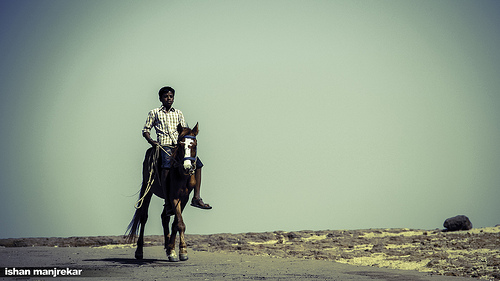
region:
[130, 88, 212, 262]
boy riding small horse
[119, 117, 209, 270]
horse with white blaze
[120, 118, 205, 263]
brown horse with white face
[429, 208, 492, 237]
single stone in field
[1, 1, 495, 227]
grey blue and white sky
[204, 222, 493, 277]
brown gound with yellow brush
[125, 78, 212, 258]
man in striped shirt on horse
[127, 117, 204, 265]
horse walking along a road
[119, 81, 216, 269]
man riding a horse on a road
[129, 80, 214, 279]
man wearing sandals on a horse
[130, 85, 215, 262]
a young boy is riding a horse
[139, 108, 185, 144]
the boy is wearing a shirt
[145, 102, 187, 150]
the shirt has long sleeves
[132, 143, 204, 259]
the horse is brown in color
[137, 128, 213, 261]
the horse is taking steps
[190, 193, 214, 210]
the boy is wearing sandals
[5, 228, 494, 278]
the terrain is rocky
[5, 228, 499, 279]
the terrain is flat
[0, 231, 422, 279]
the horse is walking along a road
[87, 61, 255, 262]
this is a person on a horse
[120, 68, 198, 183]
this is a person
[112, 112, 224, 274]
this is a horse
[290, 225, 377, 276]
this is sand on the beach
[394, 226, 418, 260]
this is sand on the beach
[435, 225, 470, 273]
this is sand on the beach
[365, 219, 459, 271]
this is sand on the beach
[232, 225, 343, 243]
this is sand on the beach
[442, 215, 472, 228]
large rock on side of road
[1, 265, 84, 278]
person's name in white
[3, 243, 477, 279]
paved road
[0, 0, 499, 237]
blue sky over the horizon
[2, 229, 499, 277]
rocky area beside road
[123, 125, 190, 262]
brown and white horse walking on road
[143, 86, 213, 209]
boy sitting on a horse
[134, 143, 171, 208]
rope in boy's hand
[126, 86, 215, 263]
boy riding a horse down a road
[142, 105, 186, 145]
white plaid shirt